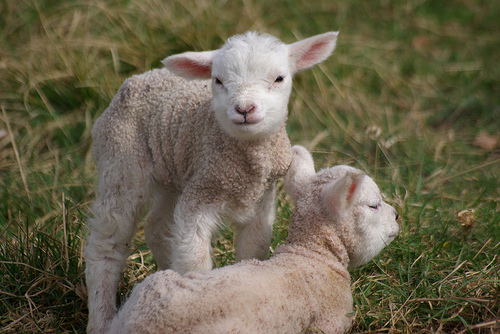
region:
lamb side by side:
[36, 23, 419, 333]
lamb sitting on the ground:
[115, 148, 411, 320]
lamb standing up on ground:
[65, 21, 314, 286]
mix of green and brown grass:
[372, 258, 494, 323]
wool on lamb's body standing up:
[116, 95, 193, 152]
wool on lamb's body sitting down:
[271, 278, 311, 290]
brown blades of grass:
[38, 16, 77, 40]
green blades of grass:
[401, 234, 422, 252]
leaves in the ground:
[391, 28, 485, 145]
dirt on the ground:
[1, 280, 57, 313]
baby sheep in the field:
[65, 10, 387, 327]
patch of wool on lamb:
[298, 284, 310, 304]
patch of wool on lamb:
[187, 299, 205, 326]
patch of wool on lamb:
[229, 299, 251, 324]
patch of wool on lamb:
[275, 278, 305, 306]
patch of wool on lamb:
[247, 298, 267, 330]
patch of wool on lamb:
[180, 203, 195, 232]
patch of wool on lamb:
[215, 141, 253, 183]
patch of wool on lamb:
[137, 122, 154, 153]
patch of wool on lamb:
[205, 157, 229, 191]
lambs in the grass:
[74, 13, 410, 332]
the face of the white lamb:
[150, 21, 348, 154]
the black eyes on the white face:
[208, 66, 287, 92]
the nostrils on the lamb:
[230, 98, 260, 123]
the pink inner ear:
[172, 55, 214, 78]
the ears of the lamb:
[284, 141, 364, 226]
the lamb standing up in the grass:
[97, 12, 344, 257]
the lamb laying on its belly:
[127, 142, 409, 332]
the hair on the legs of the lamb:
[165, 199, 223, 271]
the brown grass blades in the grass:
[0, 1, 90, 323]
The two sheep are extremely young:
[10, 15, 480, 310]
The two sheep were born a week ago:
[8, 6, 464, 317]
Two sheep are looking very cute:
[10, 15, 465, 320]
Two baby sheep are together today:
[5, 11, 470, 316]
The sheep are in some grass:
[5, 22, 495, 307]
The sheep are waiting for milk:
[5, 22, 481, 319]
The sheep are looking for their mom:
[7, 17, 489, 327]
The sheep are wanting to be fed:
[15, 15, 470, 330]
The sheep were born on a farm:
[25, 23, 478, 325]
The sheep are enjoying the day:
[10, 13, 497, 333]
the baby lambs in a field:
[78, 32, 398, 329]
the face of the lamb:
[158, 25, 338, 136]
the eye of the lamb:
[212, 73, 227, 85]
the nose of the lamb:
[231, 99, 257, 114]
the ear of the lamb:
[281, 32, 340, 68]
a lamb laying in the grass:
[100, 159, 401, 331]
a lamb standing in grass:
[88, 32, 338, 332]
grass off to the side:
[413, 66, 493, 301]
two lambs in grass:
[65, 26, 400, 329]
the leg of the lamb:
[87, 154, 135, 332]